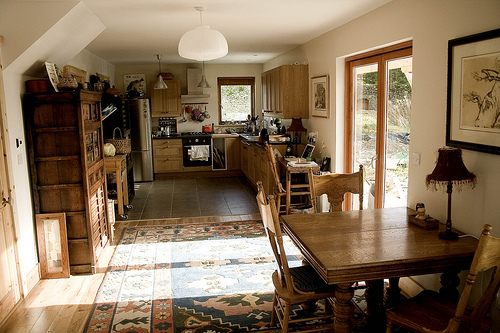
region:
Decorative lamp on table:
[422, 144, 476, 241]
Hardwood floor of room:
[1, 273, 89, 327]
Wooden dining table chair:
[253, 178, 333, 328]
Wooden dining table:
[277, 200, 498, 328]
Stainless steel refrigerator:
[111, 91, 157, 185]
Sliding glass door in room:
[336, 38, 408, 219]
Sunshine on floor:
[25, 260, 310, 304]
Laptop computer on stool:
[288, 144, 316, 166]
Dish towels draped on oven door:
[182, 145, 214, 163]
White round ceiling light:
[168, 0, 238, 61]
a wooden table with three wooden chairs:
[256, 164, 499, 331]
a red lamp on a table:
[423, 145, 475, 245]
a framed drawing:
[446, 27, 499, 156]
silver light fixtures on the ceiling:
[148, 50, 209, 89]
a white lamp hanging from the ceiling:
[178, 5, 228, 62]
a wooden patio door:
[331, 37, 411, 208]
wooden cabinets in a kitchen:
[259, 63, 309, 120]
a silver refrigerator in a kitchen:
[101, 97, 153, 182]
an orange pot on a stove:
[200, 123, 211, 132]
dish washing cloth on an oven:
[186, 145, 211, 161]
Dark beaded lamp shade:
[423, 145, 478, 192]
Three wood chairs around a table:
[252, 165, 498, 332]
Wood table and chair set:
[252, 165, 498, 331]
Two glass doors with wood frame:
[341, 39, 415, 209]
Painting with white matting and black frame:
[445, 20, 498, 160]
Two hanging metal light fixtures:
[151, 52, 211, 91]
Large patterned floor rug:
[77, 219, 430, 331]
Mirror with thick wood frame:
[34, 210, 71, 277]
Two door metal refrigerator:
[121, 96, 154, 184]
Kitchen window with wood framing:
[217, 76, 255, 126]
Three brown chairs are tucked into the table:
[216, 166, 498, 332]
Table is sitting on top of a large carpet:
[123, 166, 498, 329]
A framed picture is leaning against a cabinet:
[23, 94, 115, 281]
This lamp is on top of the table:
[409, 139, 478, 255]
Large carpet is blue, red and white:
[92, 214, 397, 329]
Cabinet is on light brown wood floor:
[19, 91, 119, 331]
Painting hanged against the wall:
[426, 26, 498, 150]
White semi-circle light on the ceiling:
[148, 1, 250, 63]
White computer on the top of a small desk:
[286, 141, 320, 175]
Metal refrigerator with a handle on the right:
[108, 96, 165, 194]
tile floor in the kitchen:
[151, 178, 228, 208]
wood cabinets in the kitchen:
[228, 132, 275, 198]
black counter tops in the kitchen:
[221, 115, 301, 145]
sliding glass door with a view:
[331, 55, 416, 211]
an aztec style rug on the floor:
[126, 229, 253, 326]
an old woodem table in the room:
[277, 205, 465, 320]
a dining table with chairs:
[226, 170, 499, 330]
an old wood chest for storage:
[18, 84, 114, 274]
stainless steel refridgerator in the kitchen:
[115, 91, 156, 185]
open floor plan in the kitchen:
[98, 52, 341, 238]